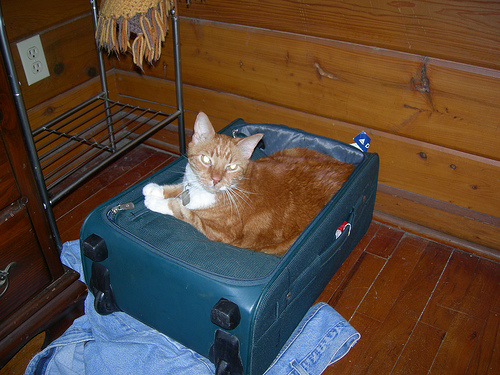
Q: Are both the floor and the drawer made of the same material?
A: Yes, both the floor and the drawer are made of wood.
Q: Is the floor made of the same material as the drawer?
A: Yes, both the floor and the drawer are made of wood.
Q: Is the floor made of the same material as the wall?
A: Yes, both the floor and the wall are made of wood.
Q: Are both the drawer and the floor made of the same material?
A: Yes, both the drawer and the floor are made of wood.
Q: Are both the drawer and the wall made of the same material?
A: Yes, both the drawer and the wall are made of wood.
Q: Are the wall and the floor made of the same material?
A: Yes, both the wall and the floor are made of wood.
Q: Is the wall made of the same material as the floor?
A: Yes, both the wall and the floor are made of wood.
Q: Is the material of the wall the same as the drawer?
A: Yes, both the wall and the drawer are made of wood.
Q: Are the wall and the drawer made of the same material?
A: Yes, both the wall and the drawer are made of wood.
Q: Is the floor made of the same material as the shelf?
A: No, the floor is made of wood and the shelf is made of metal.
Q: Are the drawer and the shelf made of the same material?
A: No, the drawer is made of wood and the shelf is made of metal.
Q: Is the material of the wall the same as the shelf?
A: No, the wall is made of wood and the shelf is made of metal.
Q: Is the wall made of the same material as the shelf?
A: No, the wall is made of wood and the shelf is made of metal.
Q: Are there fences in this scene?
A: No, there are no fences.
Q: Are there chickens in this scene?
A: No, there are no chickens.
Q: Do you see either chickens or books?
A: No, there are no chickens or books.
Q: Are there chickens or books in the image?
A: No, there are no chickens or books.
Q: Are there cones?
A: No, there are no cones.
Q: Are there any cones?
A: No, there are no cones.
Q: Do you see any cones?
A: No, there are no cones.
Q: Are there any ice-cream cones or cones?
A: No, there are no cones or ice-cream cones.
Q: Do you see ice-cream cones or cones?
A: No, there are no cones or ice-cream cones.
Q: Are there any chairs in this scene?
A: No, there are no chairs.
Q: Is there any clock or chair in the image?
A: No, there are no chairs or clocks.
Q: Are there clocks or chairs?
A: No, there are no chairs or clocks.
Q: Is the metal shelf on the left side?
A: Yes, the shelf is on the left of the image.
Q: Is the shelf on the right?
A: No, the shelf is on the left of the image.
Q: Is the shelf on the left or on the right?
A: The shelf is on the left of the image.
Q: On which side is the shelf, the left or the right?
A: The shelf is on the left of the image.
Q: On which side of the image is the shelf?
A: The shelf is on the left of the image.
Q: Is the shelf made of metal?
A: Yes, the shelf is made of metal.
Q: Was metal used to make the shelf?
A: Yes, the shelf is made of metal.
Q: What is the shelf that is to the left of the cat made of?
A: The shelf is made of metal.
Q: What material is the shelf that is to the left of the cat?
A: The shelf is made of metal.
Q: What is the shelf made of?
A: The shelf is made of metal.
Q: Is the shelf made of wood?
A: No, the shelf is made of metal.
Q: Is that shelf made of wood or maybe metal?
A: The shelf is made of metal.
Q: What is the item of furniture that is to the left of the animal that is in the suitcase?
A: The piece of furniture is a shelf.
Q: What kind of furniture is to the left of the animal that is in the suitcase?
A: The piece of furniture is a shelf.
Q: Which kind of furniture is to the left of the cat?
A: The piece of furniture is a shelf.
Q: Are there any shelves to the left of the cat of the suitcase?
A: Yes, there is a shelf to the left of the cat.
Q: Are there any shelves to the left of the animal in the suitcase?
A: Yes, there is a shelf to the left of the cat.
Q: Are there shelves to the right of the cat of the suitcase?
A: No, the shelf is to the left of the cat.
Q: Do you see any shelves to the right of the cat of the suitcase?
A: No, the shelf is to the left of the cat.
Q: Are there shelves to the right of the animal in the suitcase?
A: No, the shelf is to the left of the cat.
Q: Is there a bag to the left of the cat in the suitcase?
A: No, there is a shelf to the left of the cat.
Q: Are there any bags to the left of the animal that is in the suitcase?
A: No, there is a shelf to the left of the cat.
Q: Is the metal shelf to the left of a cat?
A: Yes, the shelf is to the left of a cat.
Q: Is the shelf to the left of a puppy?
A: No, the shelf is to the left of a cat.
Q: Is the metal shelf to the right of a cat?
A: No, the shelf is to the left of a cat.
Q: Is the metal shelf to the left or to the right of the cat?
A: The shelf is to the left of the cat.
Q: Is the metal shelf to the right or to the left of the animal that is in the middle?
A: The shelf is to the left of the cat.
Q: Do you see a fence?
A: No, there are no fences.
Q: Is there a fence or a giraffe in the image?
A: No, there are no fences or giraffes.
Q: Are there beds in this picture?
A: No, there are no beds.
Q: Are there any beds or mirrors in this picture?
A: No, there are no beds or mirrors.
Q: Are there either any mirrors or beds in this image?
A: No, there are no beds or mirrors.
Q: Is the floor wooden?
A: Yes, the floor is wooden.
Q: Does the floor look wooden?
A: Yes, the floor is wooden.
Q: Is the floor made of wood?
A: Yes, the floor is made of wood.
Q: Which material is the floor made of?
A: The floor is made of wood.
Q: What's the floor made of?
A: The floor is made of wood.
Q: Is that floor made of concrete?
A: No, the floor is made of wood.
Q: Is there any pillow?
A: No, there are no pillows.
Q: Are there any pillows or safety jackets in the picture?
A: No, there are no pillows or safety jackets.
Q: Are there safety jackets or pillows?
A: No, there are no pillows or safety jackets.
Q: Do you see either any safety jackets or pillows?
A: No, there are no pillows or safety jackets.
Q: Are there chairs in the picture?
A: No, there are no chairs.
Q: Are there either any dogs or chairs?
A: No, there are no chairs or dogs.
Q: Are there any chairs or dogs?
A: No, there are no chairs or dogs.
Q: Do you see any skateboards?
A: No, there are no skateboards.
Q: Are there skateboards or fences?
A: No, there are no skateboards or fences.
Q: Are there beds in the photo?
A: No, there are no beds.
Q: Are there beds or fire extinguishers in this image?
A: No, there are no beds or fire extinguishers.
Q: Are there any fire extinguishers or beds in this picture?
A: No, there are no beds or fire extinguishers.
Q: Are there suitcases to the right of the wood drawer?
A: Yes, there is a suitcase to the right of the drawer.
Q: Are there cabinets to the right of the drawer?
A: No, there is a suitcase to the right of the drawer.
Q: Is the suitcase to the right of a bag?
A: No, the suitcase is to the right of a drawer.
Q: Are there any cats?
A: Yes, there is a cat.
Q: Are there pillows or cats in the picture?
A: Yes, there is a cat.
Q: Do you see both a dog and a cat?
A: No, there is a cat but no dogs.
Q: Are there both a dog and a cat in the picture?
A: No, there is a cat but no dogs.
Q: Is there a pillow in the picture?
A: No, there are no pillows.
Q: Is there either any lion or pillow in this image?
A: No, there are no pillows or lions.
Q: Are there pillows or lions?
A: No, there are no pillows or lions.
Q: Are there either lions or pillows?
A: No, there are no pillows or lions.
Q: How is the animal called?
A: The animal is a cat.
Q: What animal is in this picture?
A: The animal is a cat.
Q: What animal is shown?
A: The animal is a cat.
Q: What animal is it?
A: The animal is a cat.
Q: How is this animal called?
A: This is a cat.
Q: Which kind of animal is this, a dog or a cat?
A: This is a cat.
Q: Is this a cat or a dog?
A: This is a cat.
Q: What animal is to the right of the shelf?
A: The animal is a cat.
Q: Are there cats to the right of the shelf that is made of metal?
A: Yes, there is a cat to the right of the shelf.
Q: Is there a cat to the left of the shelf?
A: No, the cat is to the right of the shelf.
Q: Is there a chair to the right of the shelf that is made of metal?
A: No, there is a cat to the right of the shelf.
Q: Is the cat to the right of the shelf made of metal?
A: Yes, the cat is to the right of the shelf.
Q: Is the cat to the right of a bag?
A: No, the cat is to the right of the shelf.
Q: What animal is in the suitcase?
A: The animal is a cat.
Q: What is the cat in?
A: The cat is in the suitcase.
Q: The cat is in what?
A: The cat is in the suitcase.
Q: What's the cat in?
A: The cat is in the suitcase.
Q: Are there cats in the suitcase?
A: Yes, there is a cat in the suitcase.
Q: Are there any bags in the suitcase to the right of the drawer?
A: No, there is a cat in the suitcase.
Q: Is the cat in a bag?
A: No, the cat is in the suitcase.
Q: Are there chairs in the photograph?
A: No, there are no chairs.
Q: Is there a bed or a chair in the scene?
A: No, there are no chairs or beds.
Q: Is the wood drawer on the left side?
A: Yes, the drawer is on the left of the image.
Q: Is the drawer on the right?
A: No, the drawer is on the left of the image.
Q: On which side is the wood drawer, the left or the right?
A: The drawer is on the left of the image.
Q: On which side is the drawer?
A: The drawer is on the left of the image.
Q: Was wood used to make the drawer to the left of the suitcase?
A: Yes, the drawer is made of wood.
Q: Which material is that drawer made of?
A: The drawer is made of wood.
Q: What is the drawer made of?
A: The drawer is made of wood.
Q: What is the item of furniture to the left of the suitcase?
A: The piece of furniture is a drawer.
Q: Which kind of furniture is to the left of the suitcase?
A: The piece of furniture is a drawer.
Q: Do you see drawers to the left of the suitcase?
A: Yes, there is a drawer to the left of the suitcase.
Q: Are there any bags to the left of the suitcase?
A: No, there is a drawer to the left of the suitcase.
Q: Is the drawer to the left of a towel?
A: No, the drawer is to the left of the suitcase.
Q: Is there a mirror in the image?
A: No, there are no mirrors.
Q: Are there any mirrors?
A: No, there are no mirrors.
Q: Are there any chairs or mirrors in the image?
A: No, there are no mirrors or chairs.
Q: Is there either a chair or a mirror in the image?
A: No, there are no mirrors or chairs.